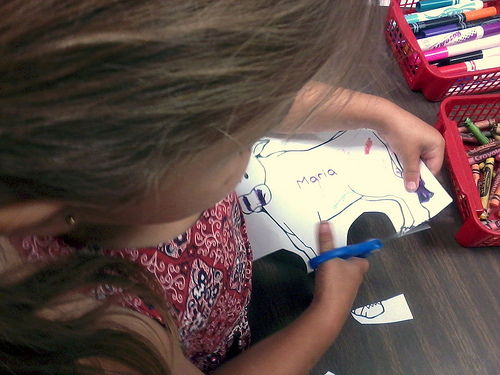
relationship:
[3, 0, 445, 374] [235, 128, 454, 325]
girl cutting paper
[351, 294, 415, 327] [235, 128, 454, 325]
piece of paper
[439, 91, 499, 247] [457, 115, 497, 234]
bin of crayons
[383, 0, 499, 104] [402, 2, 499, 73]
bin of markers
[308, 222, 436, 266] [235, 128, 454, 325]
pair cutting paper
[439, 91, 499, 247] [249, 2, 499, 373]
bin on table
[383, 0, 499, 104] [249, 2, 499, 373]
bin on table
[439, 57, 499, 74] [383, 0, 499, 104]
marker in bin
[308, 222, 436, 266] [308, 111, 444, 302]
pair in hands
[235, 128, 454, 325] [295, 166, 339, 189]
paper with maria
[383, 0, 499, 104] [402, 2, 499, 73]
bin with markers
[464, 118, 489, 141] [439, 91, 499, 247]
crayon in bin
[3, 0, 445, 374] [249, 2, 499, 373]
girl sitting at table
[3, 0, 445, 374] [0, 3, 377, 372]
girl has hair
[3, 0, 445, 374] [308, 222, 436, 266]
girl holding pair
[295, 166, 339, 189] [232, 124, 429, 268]
maria on picture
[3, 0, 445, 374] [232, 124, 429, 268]
girl cutting out cow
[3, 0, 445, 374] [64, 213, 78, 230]
girl has earring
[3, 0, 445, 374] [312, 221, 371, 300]
girl using hand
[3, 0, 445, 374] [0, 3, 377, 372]
girl has long hair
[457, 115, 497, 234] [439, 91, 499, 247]
crayons in bin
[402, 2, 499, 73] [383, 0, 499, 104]
markers in bin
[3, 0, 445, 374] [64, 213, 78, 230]
girl wearing earring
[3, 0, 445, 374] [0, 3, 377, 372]
girl with hair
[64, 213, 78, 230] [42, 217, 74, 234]
earring on ear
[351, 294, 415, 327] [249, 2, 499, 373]
piece lying on table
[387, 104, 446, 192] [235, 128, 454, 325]
hand holding paper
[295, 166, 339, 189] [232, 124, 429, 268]
maria in middle of drawing